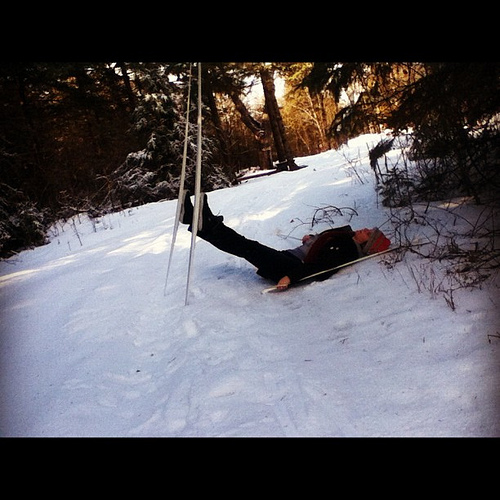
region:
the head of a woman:
[341, 210, 411, 269]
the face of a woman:
[345, 215, 394, 260]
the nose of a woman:
[350, 220, 380, 238]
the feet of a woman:
[149, 131, 291, 271]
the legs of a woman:
[183, 202, 332, 269]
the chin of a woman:
[343, 215, 368, 250]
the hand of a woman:
[262, 248, 323, 314]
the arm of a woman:
[258, 223, 388, 301]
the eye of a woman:
[347, 215, 388, 256]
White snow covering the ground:
[13, 381, 74, 416]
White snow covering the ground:
[93, 375, 145, 425]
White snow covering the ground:
[135, 366, 189, 411]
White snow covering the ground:
[173, 357, 221, 402]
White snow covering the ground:
[226, 368, 267, 412]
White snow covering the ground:
[274, 375, 349, 440]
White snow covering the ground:
[418, 373, 487, 432]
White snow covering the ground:
[298, 336, 390, 390]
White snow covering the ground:
[221, 308, 286, 358]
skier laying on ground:
[171, 65, 398, 306]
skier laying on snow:
[177, 191, 397, 298]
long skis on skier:
[156, 71, 223, 306]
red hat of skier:
[365, 228, 391, 252]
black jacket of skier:
[293, 228, 371, 285]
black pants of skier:
[207, 216, 286, 282]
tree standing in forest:
[207, 67, 310, 169]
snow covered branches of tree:
[113, 84, 205, 201]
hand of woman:
[273, 271, 296, 294]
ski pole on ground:
[261, 240, 427, 295]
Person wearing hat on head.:
[364, 231, 392, 252]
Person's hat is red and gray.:
[367, 218, 399, 264]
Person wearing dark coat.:
[326, 228, 344, 291]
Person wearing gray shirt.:
[290, 239, 305, 251]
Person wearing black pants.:
[228, 225, 275, 288]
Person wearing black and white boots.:
[182, 194, 217, 233]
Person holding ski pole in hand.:
[261, 280, 308, 325]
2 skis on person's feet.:
[148, 177, 228, 244]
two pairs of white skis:
[160, 68, 210, 303]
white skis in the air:
[155, 55, 210, 327]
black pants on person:
[194, 211, 271, 279]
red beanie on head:
[367, 219, 392, 254]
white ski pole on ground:
[281, 236, 411, 313]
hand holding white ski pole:
[257, 276, 299, 308]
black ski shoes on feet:
[195, 188, 207, 229]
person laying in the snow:
[141, 203, 442, 261]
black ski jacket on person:
[280, 216, 355, 283]